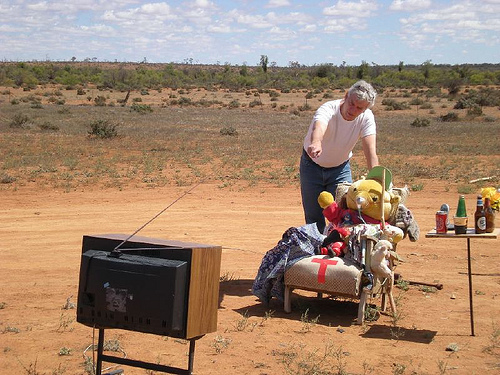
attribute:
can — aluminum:
[433, 207, 448, 239]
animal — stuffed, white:
[369, 238, 401, 320]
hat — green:
[372, 166, 399, 190]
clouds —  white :
[37, 10, 109, 42]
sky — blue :
[20, 4, 445, 64]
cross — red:
[309, 255, 338, 285]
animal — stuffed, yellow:
[320, 162, 415, 259]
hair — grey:
[334, 76, 396, 119]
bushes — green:
[1, 64, 484, 179]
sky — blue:
[9, 4, 499, 96]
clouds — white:
[313, 0, 381, 45]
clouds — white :
[123, 7, 288, 29]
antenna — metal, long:
[111, 182, 199, 261]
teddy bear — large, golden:
[348, 171, 416, 248]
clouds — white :
[1, 3, 298, 65]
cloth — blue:
[253, 223, 318, 310]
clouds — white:
[236, 8, 313, 50]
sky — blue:
[131, 9, 456, 64]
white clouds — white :
[76, 24, 121, 42]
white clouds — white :
[227, 9, 306, 31]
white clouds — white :
[401, 13, 456, 39]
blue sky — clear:
[1, 1, 498, 64]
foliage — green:
[2, 57, 494, 121]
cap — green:
[367, 162, 390, 187]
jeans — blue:
[303, 152, 355, 228]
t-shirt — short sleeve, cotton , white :
[288, 72, 378, 166]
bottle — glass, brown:
[474, 195, 486, 232]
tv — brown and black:
[76, 232, 217, 337]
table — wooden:
[424, 220, 499, 241]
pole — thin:
[461, 235, 477, 333]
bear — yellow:
[314, 162, 409, 259]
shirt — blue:
[247, 222, 325, 308]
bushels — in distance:
[67, 58, 468, 100]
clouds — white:
[166, 9, 403, 47]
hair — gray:
[345, 79, 375, 108]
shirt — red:
[277, 105, 467, 195]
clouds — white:
[97, 0, 383, 50]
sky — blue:
[3, 2, 484, 62]